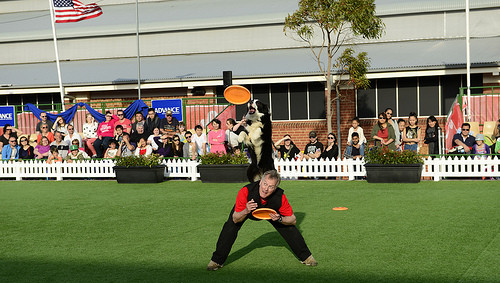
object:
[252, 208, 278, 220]
frisbee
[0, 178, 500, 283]
astroturf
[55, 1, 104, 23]
american flag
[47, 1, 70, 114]
flag pole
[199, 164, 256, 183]
planter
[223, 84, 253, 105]
frisbee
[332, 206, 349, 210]
frisbee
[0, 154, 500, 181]
fence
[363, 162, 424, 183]
flower pot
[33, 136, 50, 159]
woman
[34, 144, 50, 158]
shirt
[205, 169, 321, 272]
man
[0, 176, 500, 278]
ground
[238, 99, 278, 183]
dog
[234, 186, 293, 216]
shirt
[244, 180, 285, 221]
vest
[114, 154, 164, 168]
plants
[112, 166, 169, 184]
planter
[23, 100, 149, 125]
ribbon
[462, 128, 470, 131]
sunglasses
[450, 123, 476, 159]
man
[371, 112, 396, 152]
woman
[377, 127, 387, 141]
red shirt